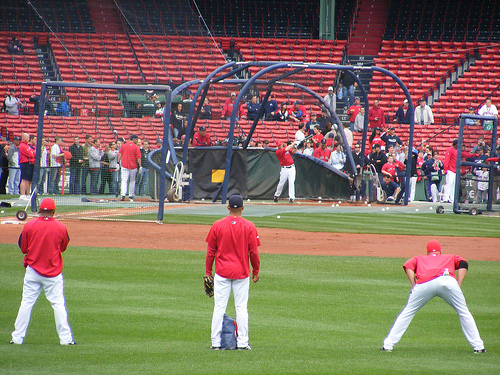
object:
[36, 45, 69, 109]
floor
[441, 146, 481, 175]
jerseys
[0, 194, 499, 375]
grass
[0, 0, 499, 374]
baseball field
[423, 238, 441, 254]
hat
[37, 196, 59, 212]
hat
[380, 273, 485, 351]
pants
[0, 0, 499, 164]
bleachers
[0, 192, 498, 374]
field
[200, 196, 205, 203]
baseballs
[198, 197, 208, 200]
baseballs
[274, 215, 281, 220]
baseballs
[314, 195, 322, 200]
baseballs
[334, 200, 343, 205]
baseballs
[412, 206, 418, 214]
baseballs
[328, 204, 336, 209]
baseballs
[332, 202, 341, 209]
baseballs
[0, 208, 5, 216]
baseballs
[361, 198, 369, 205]
baseballs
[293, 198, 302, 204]
baseballs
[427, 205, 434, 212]
baseballs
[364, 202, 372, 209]
baseballs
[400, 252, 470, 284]
baseball jersey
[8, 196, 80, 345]
man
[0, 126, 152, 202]
crowd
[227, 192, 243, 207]
hat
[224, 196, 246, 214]
head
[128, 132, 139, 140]
cap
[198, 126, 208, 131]
cap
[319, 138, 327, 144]
cap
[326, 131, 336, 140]
cap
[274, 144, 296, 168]
jersey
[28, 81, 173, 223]
metal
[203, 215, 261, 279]
baseball jersey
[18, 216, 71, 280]
baseball jersey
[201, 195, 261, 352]
man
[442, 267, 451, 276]
bottle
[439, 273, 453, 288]
pocket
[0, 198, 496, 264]
dirt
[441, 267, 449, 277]
water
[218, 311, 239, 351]
bag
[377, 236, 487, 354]
man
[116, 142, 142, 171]
jersey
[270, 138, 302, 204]
baseball batter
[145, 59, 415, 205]
frame